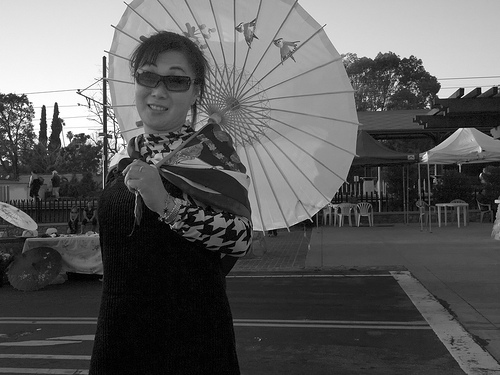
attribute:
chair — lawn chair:
[353, 199, 377, 229]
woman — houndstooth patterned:
[91, 31, 247, 343]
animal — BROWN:
[27, 171, 44, 200]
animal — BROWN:
[48, 169, 68, 198]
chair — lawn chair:
[416, 199, 436, 226]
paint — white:
[341, 260, 485, 357]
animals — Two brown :
[339, 130, 464, 229]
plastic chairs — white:
[352, 200, 376, 226]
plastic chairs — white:
[337, 200, 355, 228]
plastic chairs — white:
[322, 206, 333, 226]